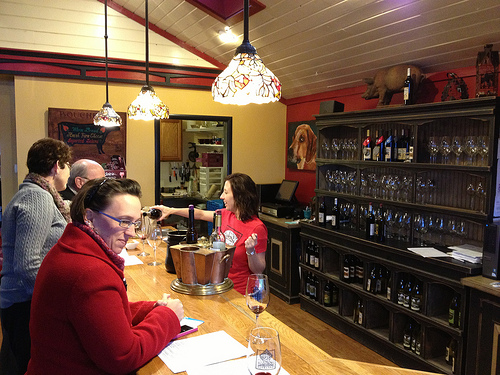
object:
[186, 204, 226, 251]
bottles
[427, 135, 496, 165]
glasses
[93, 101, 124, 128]
light shade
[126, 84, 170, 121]
light shade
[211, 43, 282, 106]
light shade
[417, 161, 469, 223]
ground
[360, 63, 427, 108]
pig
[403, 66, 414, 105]
bottle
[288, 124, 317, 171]
dog painting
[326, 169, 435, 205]
glasses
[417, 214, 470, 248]
glass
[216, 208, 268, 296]
t-shirt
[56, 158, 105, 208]
people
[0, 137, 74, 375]
people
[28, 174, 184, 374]
people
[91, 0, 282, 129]
lamp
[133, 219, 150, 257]
wineglass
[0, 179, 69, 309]
grey sweater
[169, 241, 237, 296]
bucket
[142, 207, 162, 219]
wine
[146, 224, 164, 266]
glass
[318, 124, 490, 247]
bottles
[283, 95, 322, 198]
red wall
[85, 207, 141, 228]
eyeglasses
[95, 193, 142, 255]
face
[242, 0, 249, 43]
pole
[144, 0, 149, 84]
pole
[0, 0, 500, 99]
ceiling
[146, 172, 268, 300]
bartender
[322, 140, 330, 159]
glass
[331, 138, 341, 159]
glass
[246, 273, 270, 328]
glass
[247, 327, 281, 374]
glass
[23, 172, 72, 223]
scarf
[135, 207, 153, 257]
drink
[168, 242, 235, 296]
container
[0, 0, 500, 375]
bar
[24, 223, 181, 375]
coat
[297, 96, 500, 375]
shelf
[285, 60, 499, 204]
wall